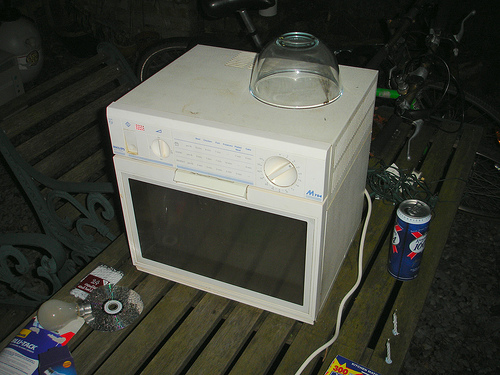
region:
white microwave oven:
[93, 36, 385, 328]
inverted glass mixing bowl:
[243, 25, 351, 114]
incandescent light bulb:
[32, 294, 100, 334]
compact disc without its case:
[79, 282, 147, 335]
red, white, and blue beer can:
[384, 197, 435, 283]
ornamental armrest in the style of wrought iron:
[11, 162, 123, 263]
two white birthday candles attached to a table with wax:
[373, 306, 405, 368]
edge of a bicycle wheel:
[130, 31, 193, 83]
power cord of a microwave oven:
[299, 186, 375, 374]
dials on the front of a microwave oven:
[106, 106, 326, 200]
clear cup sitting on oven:
[243, 28, 348, 108]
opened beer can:
[383, 191, 433, 282]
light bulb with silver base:
[32, 291, 97, 334]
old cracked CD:
[76, 285, 148, 335]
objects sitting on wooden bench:
[51, 125, 478, 372]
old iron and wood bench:
[0, 62, 167, 262]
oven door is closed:
[92, 35, 371, 320]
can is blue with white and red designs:
[387, 196, 429, 288]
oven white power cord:
[282, 189, 381, 374]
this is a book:
[326, 352, 381, 372]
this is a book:
[71, 261, 124, 296]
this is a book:
[3, 306, 83, 352]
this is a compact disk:
[85, 286, 146, 336]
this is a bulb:
[32, 301, 115, 351]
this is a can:
[385, 186, 431, 286]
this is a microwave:
[100, 40, 380, 325]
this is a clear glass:
[248, 21, 359, 109]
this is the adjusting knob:
[252, 155, 299, 200]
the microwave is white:
[95, 25, 397, 335]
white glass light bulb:
[38, 298, 94, 325]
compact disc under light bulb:
[85, 284, 146, 331]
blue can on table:
[386, 198, 431, 280]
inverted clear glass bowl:
[246, 30, 347, 107]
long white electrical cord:
[296, 187, 371, 374]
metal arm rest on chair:
[1, 140, 128, 259]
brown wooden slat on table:
[363, 120, 485, 373]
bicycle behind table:
[133, 2, 496, 125]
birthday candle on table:
[383, 337, 396, 364]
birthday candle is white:
[389, 307, 401, 337]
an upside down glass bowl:
[232, 27, 357, 134]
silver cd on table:
[84, 284, 151, 355]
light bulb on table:
[32, 287, 95, 334]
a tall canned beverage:
[365, 218, 441, 293]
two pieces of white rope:
[364, 298, 414, 372]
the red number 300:
[326, 359, 357, 374]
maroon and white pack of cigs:
[69, 250, 122, 309]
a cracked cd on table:
[80, 280, 150, 344]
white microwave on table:
[113, 62, 388, 339]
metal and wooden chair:
[20, 47, 118, 264]